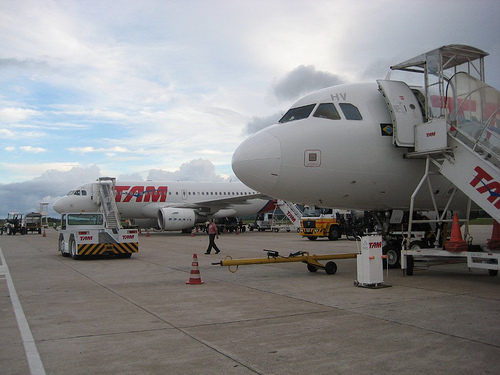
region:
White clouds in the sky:
[4, 101, 46, 153]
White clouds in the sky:
[0, 143, 37, 190]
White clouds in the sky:
[45, 153, 102, 185]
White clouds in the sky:
[43, 77, 120, 139]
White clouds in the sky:
[35, 28, 96, 75]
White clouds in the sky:
[106, 71, 160, 120]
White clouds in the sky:
[135, 116, 192, 153]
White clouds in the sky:
[138, 39, 221, 97]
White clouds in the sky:
[223, 28, 304, 73]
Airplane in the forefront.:
[221, 42, 498, 284]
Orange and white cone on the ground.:
[184, 250, 206, 288]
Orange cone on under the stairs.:
[442, 210, 469, 250]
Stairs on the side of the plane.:
[399, 43, 498, 283]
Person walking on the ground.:
[197, 213, 222, 257]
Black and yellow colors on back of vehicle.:
[73, 238, 141, 258]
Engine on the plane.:
[152, 202, 197, 234]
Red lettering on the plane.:
[108, 183, 171, 202]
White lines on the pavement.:
[0, 248, 50, 374]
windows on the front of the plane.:
[277, 103, 365, 121]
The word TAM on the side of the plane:
[111, 183, 168, 204]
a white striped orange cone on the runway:
[185, 253, 205, 285]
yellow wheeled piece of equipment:
[211, 241, 388, 276]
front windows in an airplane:
[277, 100, 362, 122]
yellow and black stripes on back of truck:
[74, 240, 136, 257]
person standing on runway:
[201, 215, 223, 255]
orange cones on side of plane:
[443, 212, 468, 253]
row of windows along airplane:
[118, 187, 260, 197]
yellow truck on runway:
[298, 213, 341, 243]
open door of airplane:
[377, 77, 426, 149]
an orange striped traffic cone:
[177, 249, 204, 290]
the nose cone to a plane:
[224, 130, 284, 201]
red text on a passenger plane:
[111, 183, 169, 207]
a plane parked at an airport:
[236, 62, 499, 254]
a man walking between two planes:
[202, 215, 222, 254]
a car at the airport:
[0, 208, 47, 239]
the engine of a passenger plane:
[152, 203, 198, 230]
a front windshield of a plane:
[274, 103, 363, 123]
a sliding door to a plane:
[378, 75, 435, 147]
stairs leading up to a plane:
[97, 185, 126, 241]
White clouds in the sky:
[8, 13, 61, 55]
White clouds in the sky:
[50, 9, 108, 62]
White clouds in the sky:
[105, 14, 159, 71]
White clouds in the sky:
[18, 87, 76, 142]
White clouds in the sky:
[76, 102, 153, 149]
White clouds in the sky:
[23, 131, 71, 157]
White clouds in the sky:
[69, 135, 138, 165]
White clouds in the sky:
[136, 54, 186, 111]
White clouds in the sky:
[195, 34, 247, 118]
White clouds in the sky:
[253, 20, 350, 65]